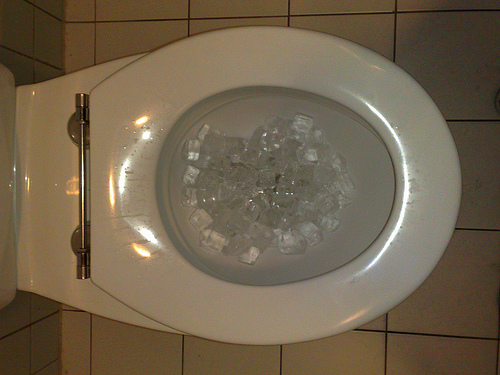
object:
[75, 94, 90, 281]
bar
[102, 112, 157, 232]
liquid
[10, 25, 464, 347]
toilet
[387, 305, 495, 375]
tile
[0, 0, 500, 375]
bathroom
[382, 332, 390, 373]
grout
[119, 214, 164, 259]
glare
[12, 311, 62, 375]
wall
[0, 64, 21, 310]
tank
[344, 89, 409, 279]
reflection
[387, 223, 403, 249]
light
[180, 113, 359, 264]
ice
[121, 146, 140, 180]
water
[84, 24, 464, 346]
lid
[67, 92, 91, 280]
hinge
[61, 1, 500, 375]
floor